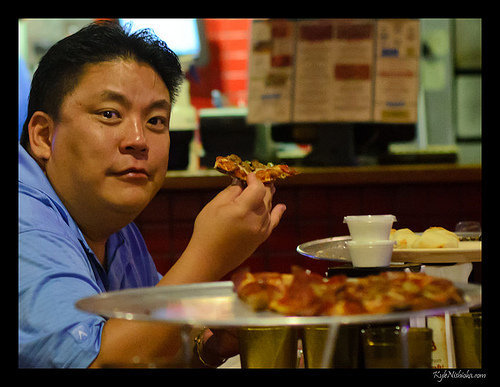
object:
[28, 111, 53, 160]
ear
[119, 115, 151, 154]
nose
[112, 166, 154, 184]
mouth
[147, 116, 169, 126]
eye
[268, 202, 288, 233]
pinky finger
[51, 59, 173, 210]
face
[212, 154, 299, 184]
piece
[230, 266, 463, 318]
pizza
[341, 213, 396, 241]
containers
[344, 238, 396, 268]
sauce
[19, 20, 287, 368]
man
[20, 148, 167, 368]
shirt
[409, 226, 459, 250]
bread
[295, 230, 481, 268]
baking sheet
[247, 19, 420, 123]
menu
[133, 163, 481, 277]
counter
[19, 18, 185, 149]
hair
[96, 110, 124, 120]
eyes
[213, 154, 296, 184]
pizza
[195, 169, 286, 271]
right hand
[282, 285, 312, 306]
pepperoni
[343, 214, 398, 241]
dressing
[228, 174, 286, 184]
crust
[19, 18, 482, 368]
pizza parlor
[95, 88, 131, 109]
eyebrow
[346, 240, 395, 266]
another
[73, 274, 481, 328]
platter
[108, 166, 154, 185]
smile